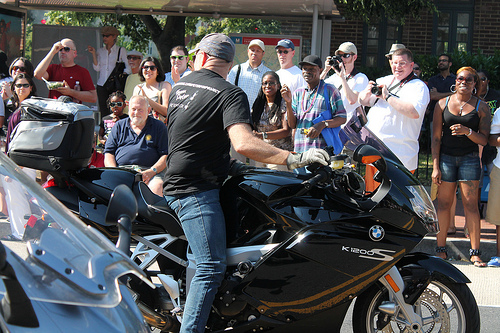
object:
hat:
[183, 32, 241, 64]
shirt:
[40, 63, 100, 104]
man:
[318, 39, 375, 136]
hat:
[331, 40, 361, 57]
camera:
[326, 51, 346, 70]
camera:
[368, 81, 388, 97]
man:
[359, 48, 431, 181]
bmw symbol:
[367, 223, 387, 242]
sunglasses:
[167, 52, 187, 60]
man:
[37, 29, 100, 133]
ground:
[408, 267, 500, 332]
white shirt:
[360, 74, 432, 172]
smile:
[395, 67, 408, 75]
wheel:
[346, 249, 484, 333]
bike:
[10, 104, 480, 332]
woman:
[0, 73, 43, 139]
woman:
[130, 55, 173, 120]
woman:
[247, 68, 298, 153]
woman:
[430, 65, 493, 270]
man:
[148, 17, 337, 332]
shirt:
[158, 68, 263, 197]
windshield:
[0, 115, 162, 311]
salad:
[39, 78, 70, 92]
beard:
[129, 115, 146, 127]